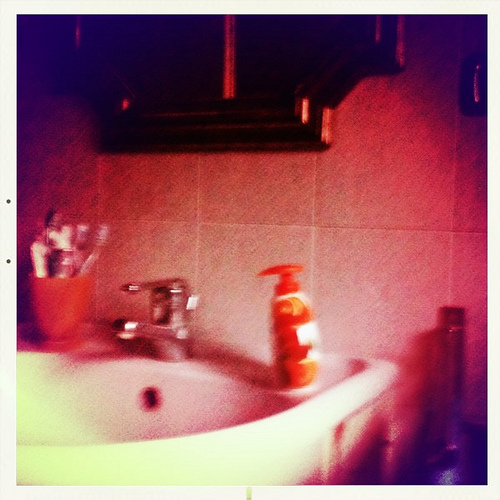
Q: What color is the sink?
A: White.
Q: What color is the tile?
A: Cream.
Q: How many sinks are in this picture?
A: One.